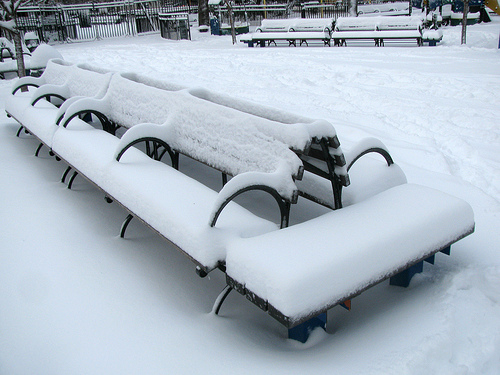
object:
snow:
[372, 40, 484, 144]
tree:
[0, 0, 28, 91]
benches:
[5, 59, 475, 343]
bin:
[219, 24, 250, 35]